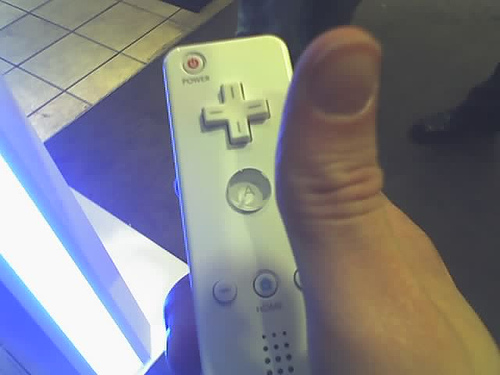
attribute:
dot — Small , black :
[261, 330, 269, 342]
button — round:
[176, 47, 208, 77]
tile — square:
[14, 27, 119, 92]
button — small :
[178, 50, 204, 76]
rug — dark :
[29, 73, 196, 214]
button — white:
[224, 164, 270, 221]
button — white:
[210, 274, 239, 306]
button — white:
[251, 266, 277, 299]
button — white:
[178, 53, 206, 75]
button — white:
[199, 79, 265, 150]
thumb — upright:
[264, 17, 499, 374]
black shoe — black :
[404, 98, 498, 152]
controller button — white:
[202, 280, 242, 305]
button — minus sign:
[227, 167, 266, 236]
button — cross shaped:
[208, 74, 280, 146]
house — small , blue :
[238, 270, 278, 295]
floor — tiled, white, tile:
[2, 0, 238, 150]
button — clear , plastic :
[226, 167, 273, 215]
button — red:
[182, 53, 204, 75]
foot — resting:
[405, 98, 486, 144]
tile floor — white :
[3, 0, 235, 153]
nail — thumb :
[302, 40, 379, 117]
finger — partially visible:
[269, 38, 419, 292]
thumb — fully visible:
[271, 22, 420, 363]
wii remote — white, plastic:
[162, 32, 309, 372]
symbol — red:
[187, 57, 199, 67]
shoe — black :
[410, 105, 466, 141]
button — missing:
[225, 165, 274, 212]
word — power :
[178, 74, 212, 83]